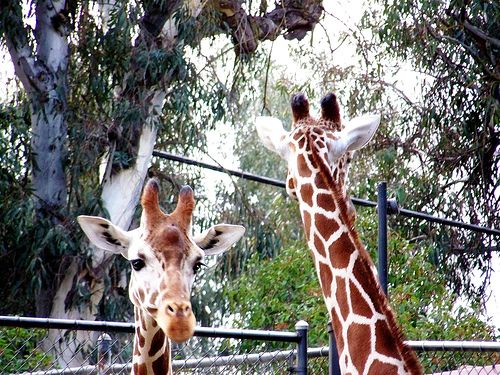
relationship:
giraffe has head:
[269, 91, 415, 369] [361, 194, 362, 195]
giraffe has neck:
[269, 91, 415, 369] [317, 220, 420, 366]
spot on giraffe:
[331, 235, 355, 267] [269, 91, 415, 369]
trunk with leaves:
[107, 41, 174, 195] [152, 66, 204, 124]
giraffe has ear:
[269, 91, 415, 369] [344, 107, 389, 154]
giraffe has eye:
[96, 165, 198, 368] [121, 251, 149, 270]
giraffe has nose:
[96, 165, 198, 368] [168, 299, 190, 312]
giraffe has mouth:
[96, 165, 198, 368] [154, 316, 195, 341]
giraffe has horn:
[269, 91, 415, 369] [323, 91, 338, 119]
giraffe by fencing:
[269, 91, 415, 369] [201, 352, 330, 373]